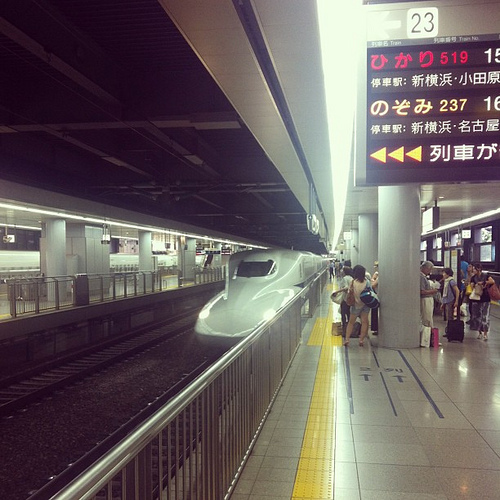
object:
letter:
[429, 145, 454, 164]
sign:
[366, 34, 499, 186]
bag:
[428, 326, 439, 350]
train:
[193, 248, 325, 353]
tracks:
[1, 305, 210, 413]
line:
[289, 282, 343, 498]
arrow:
[367, 145, 387, 163]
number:
[423, 13, 435, 31]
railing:
[47, 263, 334, 498]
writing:
[427, 141, 499, 164]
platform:
[233, 260, 497, 498]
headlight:
[265, 309, 277, 320]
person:
[341, 264, 373, 346]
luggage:
[359, 286, 381, 308]